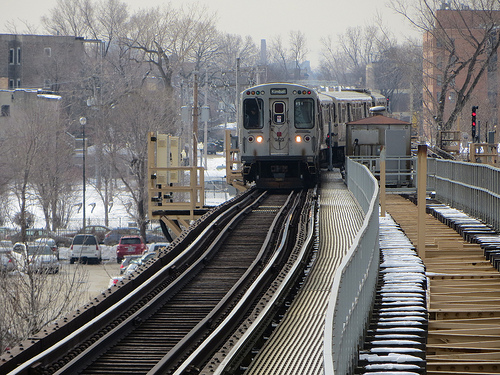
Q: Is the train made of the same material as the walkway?
A: Yes, both the train and the walkway are made of wood.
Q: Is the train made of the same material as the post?
A: Yes, both the train and the post are made of wood.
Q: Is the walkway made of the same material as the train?
A: Yes, both the walkway and the train are made of wood.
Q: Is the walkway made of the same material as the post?
A: Yes, both the walkway and the post are made of wood.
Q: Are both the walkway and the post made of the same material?
A: Yes, both the walkway and the post are made of wood.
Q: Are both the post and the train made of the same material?
A: Yes, both the post and the train are made of wood.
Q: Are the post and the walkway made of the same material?
A: Yes, both the post and the walkway are made of wood.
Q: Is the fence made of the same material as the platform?
A: Yes, both the fence and the platform are made of metal.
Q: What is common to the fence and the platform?
A: The material, both the fence and the platform are metallic.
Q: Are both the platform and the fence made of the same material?
A: Yes, both the platform and the fence are made of metal.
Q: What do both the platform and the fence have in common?
A: The material, both the platform and the fence are metallic.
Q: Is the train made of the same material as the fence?
A: No, the train is made of wood and the fence is made of metal.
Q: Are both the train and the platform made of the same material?
A: No, the train is made of wood and the platform is made of metal.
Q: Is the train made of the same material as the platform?
A: No, the train is made of wood and the platform is made of metal.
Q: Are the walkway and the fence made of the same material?
A: No, the walkway is made of wood and the fence is made of metal.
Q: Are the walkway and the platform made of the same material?
A: No, the walkway is made of wood and the platform is made of metal.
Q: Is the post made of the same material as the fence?
A: No, the post is made of wood and the fence is made of metal.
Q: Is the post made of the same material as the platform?
A: No, the post is made of wood and the platform is made of metal.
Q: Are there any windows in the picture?
A: Yes, there is a window.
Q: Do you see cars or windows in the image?
A: Yes, there is a window.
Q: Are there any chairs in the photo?
A: No, there are no chairs.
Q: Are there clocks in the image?
A: No, there are no clocks.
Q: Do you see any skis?
A: No, there are no skis.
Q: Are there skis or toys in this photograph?
A: No, there are no skis or toys.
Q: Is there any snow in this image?
A: Yes, there is snow.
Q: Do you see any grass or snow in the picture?
A: Yes, there is snow.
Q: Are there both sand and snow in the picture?
A: No, there is snow but no sand.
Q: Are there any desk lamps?
A: No, there are no desk lamps.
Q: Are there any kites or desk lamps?
A: No, there are no desk lamps or kites.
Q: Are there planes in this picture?
A: No, there are no planes.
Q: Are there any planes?
A: No, there are no planes.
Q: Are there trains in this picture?
A: Yes, there is a train.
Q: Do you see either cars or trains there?
A: Yes, there is a train.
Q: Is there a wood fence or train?
A: Yes, there is a wood train.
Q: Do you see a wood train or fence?
A: Yes, there is a wood train.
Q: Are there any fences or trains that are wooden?
A: Yes, the train is wooden.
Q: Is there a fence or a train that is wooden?
A: Yes, the train is wooden.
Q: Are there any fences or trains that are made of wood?
A: Yes, the train is made of wood.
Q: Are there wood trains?
A: Yes, there is a wood train.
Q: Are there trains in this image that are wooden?
A: Yes, there is a train that is wooden.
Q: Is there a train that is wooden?
A: Yes, there is a train that is wooden.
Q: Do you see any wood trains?
A: Yes, there is a train that is made of wood.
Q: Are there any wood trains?
A: Yes, there is a train that is made of wood.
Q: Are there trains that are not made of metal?
A: Yes, there is a train that is made of wood.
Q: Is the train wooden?
A: Yes, the train is wooden.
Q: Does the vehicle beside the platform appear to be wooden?
A: Yes, the train is wooden.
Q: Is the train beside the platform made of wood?
A: Yes, the train is made of wood.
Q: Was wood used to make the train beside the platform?
A: Yes, the train is made of wood.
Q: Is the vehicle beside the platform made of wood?
A: Yes, the train is made of wood.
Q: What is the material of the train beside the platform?
A: The train is made of wood.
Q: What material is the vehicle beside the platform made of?
A: The train is made of wood.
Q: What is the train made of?
A: The train is made of wood.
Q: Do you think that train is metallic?
A: No, the train is wooden.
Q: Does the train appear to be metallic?
A: No, the train is wooden.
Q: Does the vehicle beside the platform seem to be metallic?
A: No, the train is wooden.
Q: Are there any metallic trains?
A: No, there is a train but it is wooden.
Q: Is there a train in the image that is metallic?
A: No, there is a train but it is wooden.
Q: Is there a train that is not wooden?
A: No, there is a train but it is wooden.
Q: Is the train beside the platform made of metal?
A: No, the train is made of wood.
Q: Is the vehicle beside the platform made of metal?
A: No, the train is made of wood.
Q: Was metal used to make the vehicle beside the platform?
A: No, the train is made of wood.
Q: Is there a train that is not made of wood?
A: No, there is a train but it is made of wood.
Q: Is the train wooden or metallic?
A: The train is wooden.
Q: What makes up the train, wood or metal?
A: The train is made of wood.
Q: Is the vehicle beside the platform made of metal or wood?
A: The train is made of wood.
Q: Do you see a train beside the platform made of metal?
A: Yes, there is a train beside the platform.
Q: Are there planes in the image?
A: No, there are no planes.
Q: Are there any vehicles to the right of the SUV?
A: Yes, there is a vehicle to the right of the SUV.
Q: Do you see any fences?
A: Yes, there is a fence.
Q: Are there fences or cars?
A: Yes, there is a fence.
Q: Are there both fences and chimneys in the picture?
A: No, there is a fence but no chimneys.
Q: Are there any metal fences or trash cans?
A: Yes, there is a metal fence.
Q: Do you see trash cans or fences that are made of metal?
A: Yes, the fence is made of metal.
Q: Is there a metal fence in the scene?
A: Yes, there is a metal fence.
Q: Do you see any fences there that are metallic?
A: Yes, there is a fence that is metallic.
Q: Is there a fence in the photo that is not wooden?
A: Yes, there is a metallic fence.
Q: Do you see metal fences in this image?
A: Yes, there is a fence that is made of metal.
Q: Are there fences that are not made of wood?
A: Yes, there is a fence that is made of metal.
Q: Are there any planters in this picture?
A: No, there are no planters.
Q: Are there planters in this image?
A: No, there are no planters.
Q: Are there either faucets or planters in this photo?
A: No, there are no planters or faucets.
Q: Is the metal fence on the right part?
A: Yes, the fence is on the right of the image.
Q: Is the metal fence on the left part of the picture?
A: No, the fence is on the right of the image.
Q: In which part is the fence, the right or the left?
A: The fence is on the right of the image.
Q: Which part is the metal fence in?
A: The fence is on the right of the image.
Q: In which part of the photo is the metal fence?
A: The fence is on the right of the image.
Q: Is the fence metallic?
A: Yes, the fence is metallic.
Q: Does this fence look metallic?
A: Yes, the fence is metallic.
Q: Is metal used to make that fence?
A: Yes, the fence is made of metal.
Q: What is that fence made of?
A: The fence is made of metal.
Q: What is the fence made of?
A: The fence is made of metal.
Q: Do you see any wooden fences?
A: No, there is a fence but it is metallic.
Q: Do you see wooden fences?
A: No, there is a fence but it is metallic.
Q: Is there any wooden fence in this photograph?
A: No, there is a fence but it is metallic.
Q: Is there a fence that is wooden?
A: No, there is a fence but it is metallic.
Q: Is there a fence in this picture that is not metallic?
A: No, there is a fence but it is metallic.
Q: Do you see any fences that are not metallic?
A: No, there is a fence but it is metallic.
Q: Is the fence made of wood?
A: No, the fence is made of metal.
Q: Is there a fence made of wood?
A: No, there is a fence but it is made of metal.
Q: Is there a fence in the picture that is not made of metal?
A: No, there is a fence but it is made of metal.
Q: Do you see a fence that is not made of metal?
A: No, there is a fence but it is made of metal.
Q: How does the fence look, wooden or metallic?
A: The fence is metallic.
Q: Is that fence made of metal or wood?
A: The fence is made of metal.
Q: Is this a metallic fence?
A: Yes, this is a metallic fence.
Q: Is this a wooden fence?
A: No, this is a metallic fence.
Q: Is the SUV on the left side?
A: Yes, the SUV is on the left of the image.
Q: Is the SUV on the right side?
A: No, the SUV is on the left of the image.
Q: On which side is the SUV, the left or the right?
A: The SUV is on the left of the image.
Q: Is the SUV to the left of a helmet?
A: No, the SUV is to the left of a vehicle.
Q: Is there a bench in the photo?
A: No, there are no benches.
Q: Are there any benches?
A: No, there are no benches.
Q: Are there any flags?
A: No, there are no flags.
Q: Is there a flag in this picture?
A: No, there are no flags.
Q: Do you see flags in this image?
A: No, there are no flags.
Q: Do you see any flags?
A: No, there are no flags.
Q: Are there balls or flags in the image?
A: No, there are no flags or balls.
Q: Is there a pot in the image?
A: No, there are no pots.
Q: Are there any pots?
A: No, there are no pots.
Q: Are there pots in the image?
A: No, there are no pots.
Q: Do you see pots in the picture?
A: No, there are no pots.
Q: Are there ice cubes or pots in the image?
A: No, there are no pots or ice cubes.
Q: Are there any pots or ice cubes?
A: No, there are no pots or ice cubes.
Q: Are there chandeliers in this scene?
A: No, there are no chandeliers.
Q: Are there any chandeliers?
A: No, there are no chandeliers.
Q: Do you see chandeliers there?
A: No, there are no chandeliers.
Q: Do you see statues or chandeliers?
A: No, there are no chandeliers or statues.